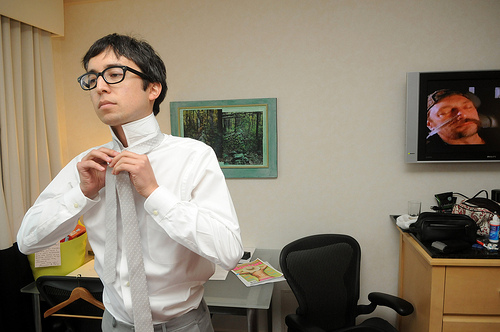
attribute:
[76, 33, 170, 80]
hair — short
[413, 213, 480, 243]
kit — shaving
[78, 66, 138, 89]
glasses — black, thick-rimmed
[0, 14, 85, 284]
curtains — cream-colored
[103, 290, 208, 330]
bottoms — grey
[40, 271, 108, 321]
hanger — wooden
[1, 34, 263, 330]
boy — black